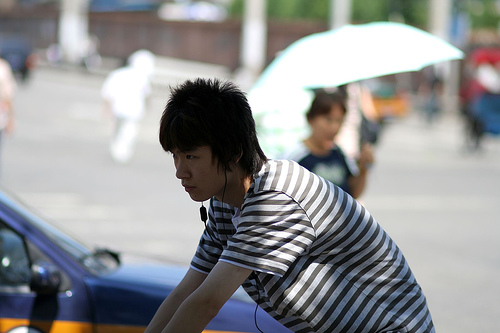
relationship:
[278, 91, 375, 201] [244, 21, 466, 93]
person holds umbrella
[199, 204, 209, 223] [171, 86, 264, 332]
volume on headphones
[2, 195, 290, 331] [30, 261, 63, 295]
car has mirror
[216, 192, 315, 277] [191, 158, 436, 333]
sleeve of shirt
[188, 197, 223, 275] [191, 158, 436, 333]
sleeve of shirt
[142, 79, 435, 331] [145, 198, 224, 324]
guy has arm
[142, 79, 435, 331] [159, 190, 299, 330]
guy has arm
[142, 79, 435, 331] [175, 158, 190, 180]
guy has nose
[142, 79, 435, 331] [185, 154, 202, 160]
guy has eye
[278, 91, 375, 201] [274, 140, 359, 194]
person wearing shirt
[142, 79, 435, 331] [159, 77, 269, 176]
guy has hair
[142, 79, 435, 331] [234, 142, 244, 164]
guy has ear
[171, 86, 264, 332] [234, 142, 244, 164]
headphones in ear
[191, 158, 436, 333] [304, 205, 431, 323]
shirt has shadow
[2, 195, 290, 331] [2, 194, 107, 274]
car has windshield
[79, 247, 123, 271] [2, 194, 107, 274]
wiper on windshield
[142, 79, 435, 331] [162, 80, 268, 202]
guy has head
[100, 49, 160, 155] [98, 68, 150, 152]
person in suit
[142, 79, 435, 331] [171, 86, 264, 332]
guy has headphones